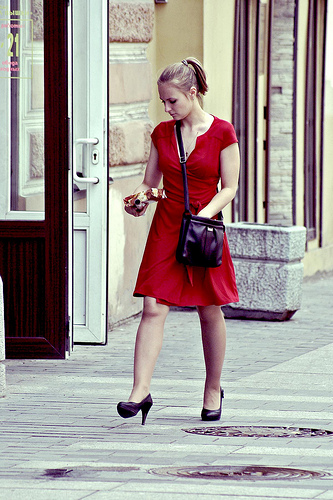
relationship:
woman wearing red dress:
[116, 57, 239, 424] [135, 116, 242, 308]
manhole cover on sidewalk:
[183, 426, 330, 439] [1, 266, 331, 498]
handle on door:
[74, 138, 100, 185] [3, 3, 106, 344]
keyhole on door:
[89, 147, 99, 166] [3, 3, 106, 344]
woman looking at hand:
[116, 57, 239, 424] [122, 194, 148, 216]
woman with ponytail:
[116, 57, 239, 424] [184, 56, 209, 96]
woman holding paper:
[116, 57, 239, 424] [129, 187, 168, 211]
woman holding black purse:
[116, 57, 239, 424] [172, 116, 224, 267]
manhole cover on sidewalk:
[147, 464, 329, 482] [1, 266, 331, 498]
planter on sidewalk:
[221, 220, 304, 324] [1, 266, 331, 498]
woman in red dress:
[116, 57, 239, 424] [135, 116, 242, 308]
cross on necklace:
[183, 150, 190, 157] [174, 111, 211, 159]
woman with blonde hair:
[116, 57, 239, 424] [155, 57, 208, 109]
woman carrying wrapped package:
[116, 57, 239, 424] [122, 186, 166, 207]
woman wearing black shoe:
[116, 57, 239, 424] [116, 393, 154, 426]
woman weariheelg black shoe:
[116, 57, 239, 424] [118, 393, 152, 426]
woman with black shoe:
[116, 57, 239, 424] [118, 393, 152, 426]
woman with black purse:
[116, 57, 239, 424] [172, 116, 224, 267]